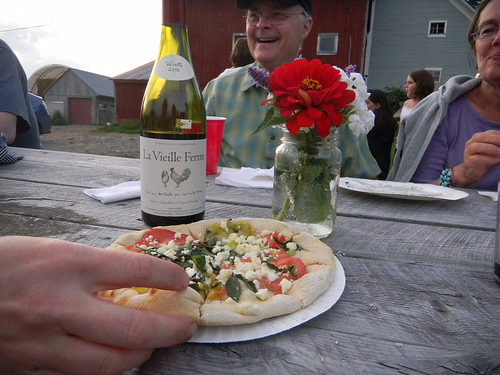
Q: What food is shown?
A: Pizza.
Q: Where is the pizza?
A: On a plate.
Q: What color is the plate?
A: White.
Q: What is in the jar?
A: Flowers.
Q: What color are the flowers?
A: Red.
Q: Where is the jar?
A: On the table.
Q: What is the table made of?
A: Wood.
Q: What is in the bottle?
A: Wine.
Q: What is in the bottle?
A: Wine.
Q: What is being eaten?
A: Pizza.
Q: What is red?
A: Flower.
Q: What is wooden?
A: Table.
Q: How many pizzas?
A: One.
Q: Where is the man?
A: Left of the woman.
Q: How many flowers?
A: One.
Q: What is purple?
A: Shirt.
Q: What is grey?
A: Sweater.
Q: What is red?
A: Flowers.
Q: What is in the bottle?
A: Wine.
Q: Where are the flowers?
A: Jar.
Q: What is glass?
A: Bottle.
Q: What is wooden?
A: Table.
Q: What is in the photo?
A: The people.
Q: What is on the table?
A: Food.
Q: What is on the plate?
A: Pizza.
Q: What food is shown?
A: Pizza.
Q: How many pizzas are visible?
A: One.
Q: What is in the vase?
A: Flowers.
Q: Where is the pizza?
A: On a plate.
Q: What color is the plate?
A: White.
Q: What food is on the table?
A: Pizza.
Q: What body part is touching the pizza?
A: Hands.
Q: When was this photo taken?
A: Lunch or dinner time.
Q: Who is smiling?
A: The man and woman.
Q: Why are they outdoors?
A: It is a nice day to eat outside.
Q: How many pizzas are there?
A: One.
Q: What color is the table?
A: Gray.